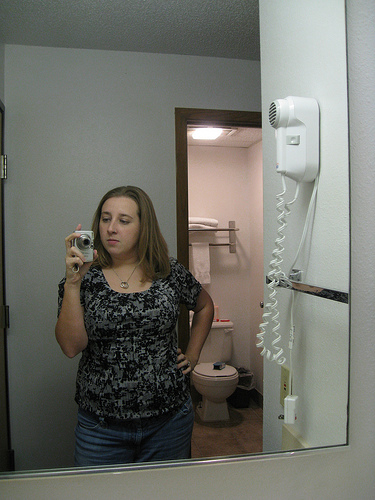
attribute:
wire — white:
[250, 193, 291, 367]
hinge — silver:
[0, 153, 15, 184]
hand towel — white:
[188, 237, 214, 287]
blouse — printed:
[77, 278, 188, 408]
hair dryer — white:
[246, 72, 330, 204]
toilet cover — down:
[191, 361, 242, 379]